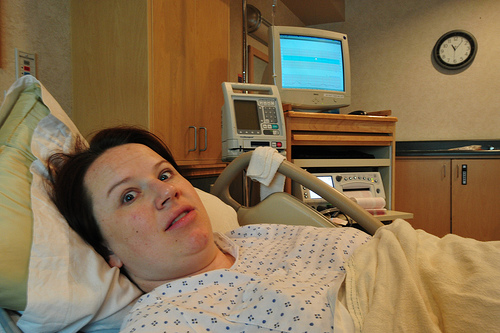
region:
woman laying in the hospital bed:
[59, 106, 497, 322]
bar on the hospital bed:
[218, 141, 388, 234]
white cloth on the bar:
[245, 136, 282, 196]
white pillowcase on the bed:
[4, 78, 224, 330]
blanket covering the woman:
[344, 215, 498, 332]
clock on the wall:
[428, 21, 478, 73]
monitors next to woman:
[222, 16, 374, 216]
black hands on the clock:
[449, 41, 463, 52]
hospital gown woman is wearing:
[158, 219, 368, 331]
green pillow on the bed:
[3, 101, 55, 301]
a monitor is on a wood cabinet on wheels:
[266, 24, 351, 108]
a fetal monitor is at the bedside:
[298, 160, 393, 217]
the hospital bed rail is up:
[210, 145, 387, 272]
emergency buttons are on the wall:
[10, 45, 42, 92]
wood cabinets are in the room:
[393, 139, 498, 239]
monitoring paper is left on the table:
[339, 191, 388, 216]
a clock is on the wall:
[425, 27, 482, 74]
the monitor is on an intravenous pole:
[217, 5, 292, 201]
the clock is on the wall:
[428, 28, 486, 80]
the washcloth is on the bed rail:
[244, 142, 290, 187]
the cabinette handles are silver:
[177, 118, 216, 154]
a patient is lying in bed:
[20, 7, 497, 324]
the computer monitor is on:
[269, 22, 363, 110]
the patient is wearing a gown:
[219, 215, 341, 328]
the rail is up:
[222, 149, 374, 224]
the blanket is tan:
[363, 223, 477, 326]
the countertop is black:
[404, 132, 466, 152]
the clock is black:
[424, 13, 483, 83]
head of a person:
[56, 112, 223, 282]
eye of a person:
[149, 160, 188, 182]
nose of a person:
[150, 182, 194, 207]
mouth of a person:
[165, 202, 202, 236]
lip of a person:
[165, 202, 195, 236]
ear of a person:
[96, 242, 142, 282]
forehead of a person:
[68, 132, 156, 216]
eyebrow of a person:
[100, 172, 134, 192]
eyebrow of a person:
[142, 147, 182, 171]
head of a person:
[53, 120, 233, 279]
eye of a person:
[111, 172, 154, 219]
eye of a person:
[148, 162, 184, 184]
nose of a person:
[143, 182, 186, 215]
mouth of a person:
[163, 201, 202, 245]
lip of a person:
[163, 197, 203, 247]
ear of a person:
[96, 241, 147, 273]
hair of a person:
[40, 184, 82, 256]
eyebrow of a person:
[108, 171, 145, 201]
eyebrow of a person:
[148, 152, 171, 172]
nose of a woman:
[137, 177, 183, 209]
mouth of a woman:
[158, 203, 219, 244]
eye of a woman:
[113, 180, 141, 210]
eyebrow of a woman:
[102, 175, 135, 200]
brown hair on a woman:
[31, 121, 176, 235]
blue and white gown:
[140, 194, 364, 330]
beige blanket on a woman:
[323, 208, 493, 332]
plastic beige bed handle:
[208, 134, 394, 234]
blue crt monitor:
[271, 20, 364, 105]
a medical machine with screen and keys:
[208, 72, 287, 157]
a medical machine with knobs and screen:
[310, 167, 392, 204]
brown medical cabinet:
[392, 143, 499, 235]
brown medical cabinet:
[72, 3, 224, 154]